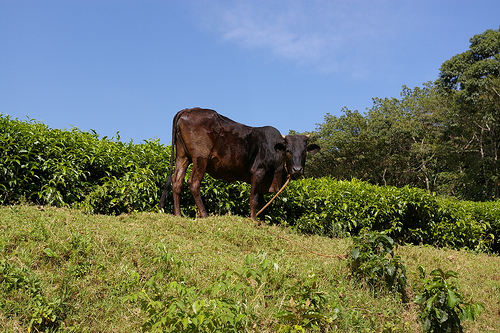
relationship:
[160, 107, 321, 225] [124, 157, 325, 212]
cow standing near bushes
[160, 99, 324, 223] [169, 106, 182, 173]
cow has tail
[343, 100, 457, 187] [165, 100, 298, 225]
trees near cow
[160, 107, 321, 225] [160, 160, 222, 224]
cow has legs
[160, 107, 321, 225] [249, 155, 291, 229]
cow wearing rope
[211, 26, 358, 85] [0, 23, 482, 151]
cloud in sky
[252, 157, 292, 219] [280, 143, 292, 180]
rope tied to cows neck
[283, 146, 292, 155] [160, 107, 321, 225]
eye on cow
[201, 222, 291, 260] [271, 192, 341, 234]
dirt with plant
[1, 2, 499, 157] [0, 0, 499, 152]
sky with cloud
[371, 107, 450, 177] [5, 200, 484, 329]
trees in field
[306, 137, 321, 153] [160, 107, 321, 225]
ear on cow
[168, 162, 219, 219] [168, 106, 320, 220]
leg on cow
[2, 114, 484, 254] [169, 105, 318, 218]
bushes behind animal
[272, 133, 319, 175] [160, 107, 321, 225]
face of cow